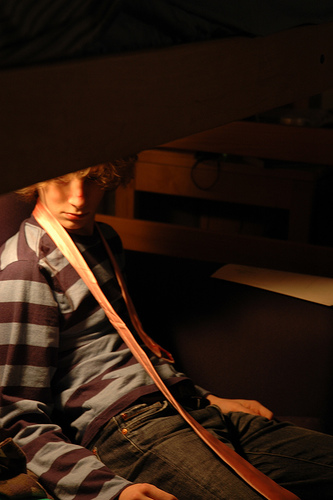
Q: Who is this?
A: Man.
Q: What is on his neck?
A: Tie.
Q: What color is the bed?
A: Brown.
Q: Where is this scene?
A: In a bedroom.